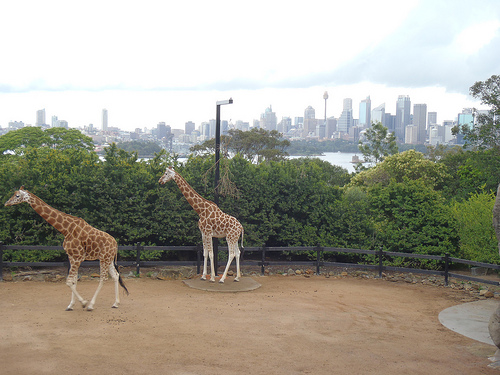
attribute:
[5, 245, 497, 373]
pen — sandy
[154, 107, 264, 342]
long neck — on giraffe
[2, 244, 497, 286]
wooden fence — gray 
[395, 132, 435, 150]
ground — under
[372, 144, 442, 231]
tree — under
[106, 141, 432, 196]
water — blue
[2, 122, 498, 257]
tree grove — standing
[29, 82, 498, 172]
cityscape — behind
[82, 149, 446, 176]
water — blue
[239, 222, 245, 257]
tail — green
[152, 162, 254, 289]
giraffe — standing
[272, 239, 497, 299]
fence giraffes — on giraffe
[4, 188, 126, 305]
giraffe — standing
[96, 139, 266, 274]
giraffes — brown 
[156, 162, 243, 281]
giraffe — TALL , behind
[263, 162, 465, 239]
trees — green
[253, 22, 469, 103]
sky — white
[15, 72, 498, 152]
skyline — large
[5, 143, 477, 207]
bushes — behind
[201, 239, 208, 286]
leg — on giraffe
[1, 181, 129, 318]
giraffe — TALL 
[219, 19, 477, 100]
cloud — large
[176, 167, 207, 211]
neck — long